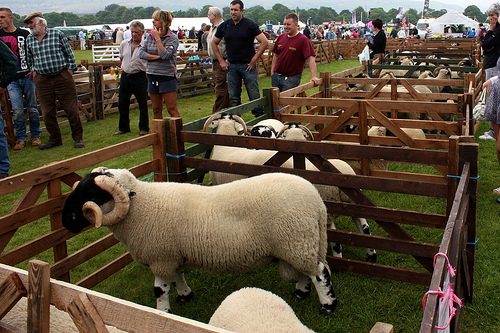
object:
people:
[1, 1, 500, 203]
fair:
[0, 0, 499, 332]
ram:
[61, 165, 337, 315]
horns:
[80, 173, 132, 229]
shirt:
[273, 31, 316, 75]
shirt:
[24, 28, 77, 74]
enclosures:
[0, 38, 486, 332]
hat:
[23, 12, 46, 23]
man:
[23, 12, 87, 150]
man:
[270, 13, 322, 93]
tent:
[123, 16, 213, 40]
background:
[0, 0, 499, 44]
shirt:
[214, 16, 262, 63]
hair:
[34, 16, 48, 29]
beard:
[30, 20, 41, 37]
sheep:
[199, 112, 378, 265]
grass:
[0, 49, 499, 332]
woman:
[140, 9, 181, 118]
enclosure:
[1, 119, 479, 332]